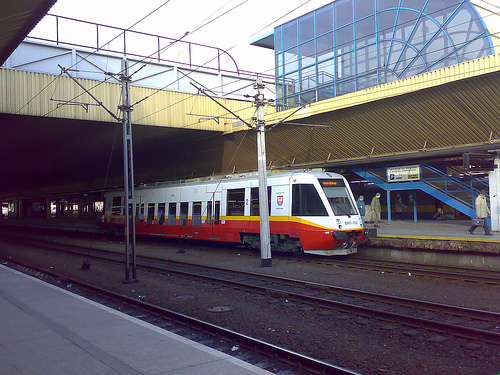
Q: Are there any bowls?
A: No, there are no bowls.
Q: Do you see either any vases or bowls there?
A: No, there are no bowls or vases.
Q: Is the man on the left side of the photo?
A: No, the man is on the right of the image.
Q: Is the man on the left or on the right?
A: The man is on the right of the image.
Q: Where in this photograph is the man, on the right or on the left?
A: The man is on the right of the image.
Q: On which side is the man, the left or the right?
A: The man is on the right of the image.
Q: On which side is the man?
A: The man is on the right of the image.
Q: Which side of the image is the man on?
A: The man is on the right of the image.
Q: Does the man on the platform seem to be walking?
A: Yes, the man is walking.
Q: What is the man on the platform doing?
A: The man is walking.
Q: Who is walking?
A: The man is walking.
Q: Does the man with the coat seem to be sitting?
A: No, the man is walking.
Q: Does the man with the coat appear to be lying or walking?
A: The man is walking.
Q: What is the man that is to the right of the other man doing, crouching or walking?
A: The man is walking.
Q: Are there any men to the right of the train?
A: Yes, there is a man to the right of the train.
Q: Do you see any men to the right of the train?
A: Yes, there is a man to the right of the train.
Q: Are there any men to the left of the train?
A: No, the man is to the right of the train.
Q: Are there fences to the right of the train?
A: No, there is a man to the right of the train.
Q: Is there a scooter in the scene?
A: No, there are no scooters.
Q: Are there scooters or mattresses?
A: No, there are no scooters or mattresses.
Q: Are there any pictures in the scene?
A: No, there are no pictures.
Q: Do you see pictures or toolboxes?
A: No, there are no pictures or toolboxes.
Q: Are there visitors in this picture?
A: No, there are no visitors.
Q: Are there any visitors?
A: No, there are no visitors.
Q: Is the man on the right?
A: Yes, the man is on the right of the image.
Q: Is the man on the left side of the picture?
A: No, the man is on the right of the image.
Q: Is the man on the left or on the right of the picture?
A: The man is on the right of the image.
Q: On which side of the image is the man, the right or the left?
A: The man is on the right of the image.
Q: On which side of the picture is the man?
A: The man is on the right of the image.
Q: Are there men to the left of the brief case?
A: Yes, there is a man to the left of the brief case.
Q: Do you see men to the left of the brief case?
A: Yes, there is a man to the left of the brief case.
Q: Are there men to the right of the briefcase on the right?
A: No, the man is to the left of the briefcase.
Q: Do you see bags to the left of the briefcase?
A: No, there is a man to the left of the briefcase.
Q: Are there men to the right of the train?
A: Yes, there is a man to the right of the train.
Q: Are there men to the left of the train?
A: No, the man is to the right of the train.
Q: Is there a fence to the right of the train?
A: No, there is a man to the right of the train.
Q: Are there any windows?
A: Yes, there are windows.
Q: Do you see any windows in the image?
A: Yes, there are windows.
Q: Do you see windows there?
A: Yes, there are windows.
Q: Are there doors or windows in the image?
A: Yes, there are windows.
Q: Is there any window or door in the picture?
A: Yes, there are windows.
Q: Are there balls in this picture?
A: No, there are no balls.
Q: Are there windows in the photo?
A: Yes, there is a window.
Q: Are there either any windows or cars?
A: Yes, there is a window.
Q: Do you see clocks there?
A: No, there are no clocks.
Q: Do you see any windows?
A: Yes, there is a window.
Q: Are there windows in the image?
A: Yes, there is a window.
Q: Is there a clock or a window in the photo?
A: Yes, there is a window.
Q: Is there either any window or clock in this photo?
A: Yes, there is a window.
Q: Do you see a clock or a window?
A: Yes, there is a window.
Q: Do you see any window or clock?
A: Yes, there is a window.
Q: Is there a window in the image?
A: Yes, there is a window.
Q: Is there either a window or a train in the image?
A: Yes, there is a window.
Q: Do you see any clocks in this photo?
A: No, there are no clocks.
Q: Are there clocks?
A: No, there are no clocks.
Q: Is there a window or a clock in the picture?
A: Yes, there is a window.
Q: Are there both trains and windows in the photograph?
A: Yes, there are both a window and a train.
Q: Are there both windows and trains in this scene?
A: Yes, there are both a window and a train.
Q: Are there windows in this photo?
A: Yes, there is a window.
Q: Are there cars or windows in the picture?
A: Yes, there is a window.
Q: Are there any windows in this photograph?
A: Yes, there is a window.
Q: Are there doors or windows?
A: Yes, there is a window.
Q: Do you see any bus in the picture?
A: No, there are no buses.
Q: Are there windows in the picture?
A: Yes, there is a window.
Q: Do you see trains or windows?
A: Yes, there is a window.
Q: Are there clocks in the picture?
A: No, there are no clocks.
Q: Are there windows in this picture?
A: Yes, there is a window.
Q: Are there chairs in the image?
A: No, there are no chairs.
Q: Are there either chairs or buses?
A: No, there are no chairs or buses.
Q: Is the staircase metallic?
A: Yes, the staircase is metallic.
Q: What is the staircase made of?
A: The staircase is made of metal.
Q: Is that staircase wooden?
A: No, the staircase is metallic.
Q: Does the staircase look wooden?
A: No, the staircase is metallic.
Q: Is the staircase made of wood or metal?
A: The staircase is made of metal.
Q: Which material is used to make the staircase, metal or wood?
A: The staircase is made of metal.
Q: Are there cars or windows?
A: Yes, there are windows.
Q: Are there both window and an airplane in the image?
A: No, there are windows but no airplanes.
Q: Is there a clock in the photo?
A: No, there are no clocks.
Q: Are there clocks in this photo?
A: No, there are no clocks.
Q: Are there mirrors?
A: No, there are no mirrors.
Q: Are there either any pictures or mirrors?
A: No, there are no mirrors or pictures.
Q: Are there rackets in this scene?
A: No, there are no rackets.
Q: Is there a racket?
A: No, there are no rackets.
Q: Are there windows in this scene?
A: Yes, there is a window.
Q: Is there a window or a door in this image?
A: Yes, there is a window.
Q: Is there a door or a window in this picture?
A: Yes, there is a window.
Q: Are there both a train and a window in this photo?
A: Yes, there are both a window and a train.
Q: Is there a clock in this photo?
A: No, there are no clocks.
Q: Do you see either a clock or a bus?
A: No, there are no clocks or buses.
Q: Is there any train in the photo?
A: Yes, there is a train.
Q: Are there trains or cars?
A: Yes, there is a train.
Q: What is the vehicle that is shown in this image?
A: The vehicle is a train.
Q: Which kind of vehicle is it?
A: The vehicle is a train.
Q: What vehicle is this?
A: This is a train.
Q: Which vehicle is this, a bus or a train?
A: This is a train.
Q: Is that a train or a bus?
A: That is a train.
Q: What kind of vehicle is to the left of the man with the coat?
A: The vehicle is a train.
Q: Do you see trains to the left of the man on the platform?
A: Yes, there is a train to the left of the man.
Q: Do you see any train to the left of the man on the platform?
A: Yes, there is a train to the left of the man.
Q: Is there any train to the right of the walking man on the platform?
A: No, the train is to the left of the man.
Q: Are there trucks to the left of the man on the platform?
A: No, there is a train to the left of the man.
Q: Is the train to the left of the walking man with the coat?
A: Yes, the train is to the left of the man.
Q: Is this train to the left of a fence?
A: No, the train is to the left of the man.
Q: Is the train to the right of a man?
A: No, the train is to the left of a man.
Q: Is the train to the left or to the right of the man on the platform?
A: The train is to the left of the man.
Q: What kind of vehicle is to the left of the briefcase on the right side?
A: The vehicle is a train.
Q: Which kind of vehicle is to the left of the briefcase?
A: The vehicle is a train.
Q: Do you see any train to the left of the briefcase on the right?
A: Yes, there is a train to the left of the briefcase.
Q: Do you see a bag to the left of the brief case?
A: No, there is a train to the left of the brief case.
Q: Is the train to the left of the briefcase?
A: Yes, the train is to the left of the briefcase.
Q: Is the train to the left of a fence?
A: No, the train is to the left of the briefcase.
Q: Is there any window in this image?
A: Yes, there is a window.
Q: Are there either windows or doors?
A: Yes, there is a window.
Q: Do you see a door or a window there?
A: Yes, there is a window.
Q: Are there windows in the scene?
A: Yes, there is a window.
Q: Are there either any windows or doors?
A: Yes, there is a window.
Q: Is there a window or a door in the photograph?
A: Yes, there is a window.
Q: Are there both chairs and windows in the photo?
A: No, there is a window but no chairs.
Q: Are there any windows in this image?
A: Yes, there is a window.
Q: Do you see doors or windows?
A: Yes, there is a window.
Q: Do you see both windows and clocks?
A: No, there is a window but no clocks.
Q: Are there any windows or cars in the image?
A: Yes, there is a window.